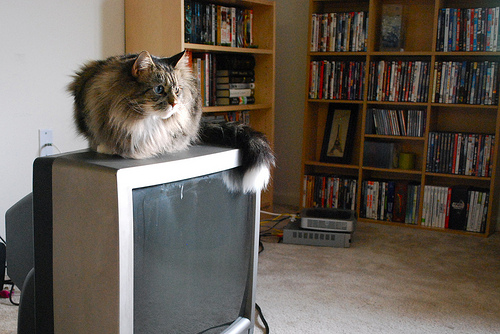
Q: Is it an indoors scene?
A: Yes, it is indoors.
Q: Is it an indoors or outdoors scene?
A: It is indoors.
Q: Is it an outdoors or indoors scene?
A: It is indoors.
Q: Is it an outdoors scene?
A: No, it is indoors.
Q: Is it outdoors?
A: No, it is indoors.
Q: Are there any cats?
A: Yes, there is a cat.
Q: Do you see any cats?
A: Yes, there is a cat.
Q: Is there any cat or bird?
A: Yes, there is a cat.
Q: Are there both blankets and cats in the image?
A: No, there is a cat but no blankets.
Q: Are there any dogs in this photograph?
A: No, there are no dogs.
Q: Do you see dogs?
A: No, there are no dogs.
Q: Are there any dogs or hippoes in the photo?
A: No, there are no dogs or hippoes.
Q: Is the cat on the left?
A: Yes, the cat is on the left of the image.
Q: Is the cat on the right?
A: No, the cat is on the left of the image.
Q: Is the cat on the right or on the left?
A: The cat is on the left of the image.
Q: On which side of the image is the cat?
A: The cat is on the left of the image.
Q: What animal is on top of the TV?
A: The cat is on top of the TV.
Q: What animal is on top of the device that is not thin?
A: The cat is on top of the TV.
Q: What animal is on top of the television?
A: The cat is on top of the TV.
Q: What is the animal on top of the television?
A: The animal is a cat.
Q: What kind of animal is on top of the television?
A: The animal is a cat.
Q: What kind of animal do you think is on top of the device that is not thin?
A: The animal is a cat.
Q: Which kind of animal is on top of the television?
A: The animal is a cat.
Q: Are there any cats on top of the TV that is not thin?
A: Yes, there is a cat on top of the television.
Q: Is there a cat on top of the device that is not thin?
A: Yes, there is a cat on top of the television.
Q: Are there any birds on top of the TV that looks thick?
A: No, there is a cat on top of the TV.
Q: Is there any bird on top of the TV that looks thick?
A: No, there is a cat on top of the TV.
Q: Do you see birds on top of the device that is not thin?
A: No, there is a cat on top of the TV.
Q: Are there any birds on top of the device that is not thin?
A: No, there is a cat on top of the TV.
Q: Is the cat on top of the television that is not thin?
A: Yes, the cat is on top of the TV.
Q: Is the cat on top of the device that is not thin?
A: Yes, the cat is on top of the TV.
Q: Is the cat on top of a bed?
A: No, the cat is on top of the TV.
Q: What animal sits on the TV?
A: The cat sits on the TV.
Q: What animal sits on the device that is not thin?
A: The cat sits on the TV.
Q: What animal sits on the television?
A: The cat sits on the TV.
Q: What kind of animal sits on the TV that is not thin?
A: The animal is a cat.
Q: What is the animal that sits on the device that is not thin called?
A: The animal is a cat.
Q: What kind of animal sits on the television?
A: The animal is a cat.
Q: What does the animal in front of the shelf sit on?
A: The cat sits on the television.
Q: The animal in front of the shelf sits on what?
A: The cat sits on the television.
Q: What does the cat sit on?
A: The cat sits on the television.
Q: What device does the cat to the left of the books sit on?
A: The cat sits on the television.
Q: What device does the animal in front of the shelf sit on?
A: The cat sits on the television.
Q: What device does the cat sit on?
A: The cat sits on the television.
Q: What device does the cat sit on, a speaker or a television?
A: The cat sits on a television.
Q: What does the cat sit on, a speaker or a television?
A: The cat sits on a television.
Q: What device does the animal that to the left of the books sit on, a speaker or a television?
A: The cat sits on a television.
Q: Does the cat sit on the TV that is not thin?
A: Yes, the cat sits on the TV.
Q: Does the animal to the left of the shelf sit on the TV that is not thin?
A: Yes, the cat sits on the TV.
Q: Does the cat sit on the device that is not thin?
A: Yes, the cat sits on the TV.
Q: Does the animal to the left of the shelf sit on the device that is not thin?
A: Yes, the cat sits on the TV.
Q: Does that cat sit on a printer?
A: No, the cat sits on the TV.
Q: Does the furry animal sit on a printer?
A: No, the cat sits on the TV.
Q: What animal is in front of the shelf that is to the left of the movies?
A: The cat is in front of the shelf.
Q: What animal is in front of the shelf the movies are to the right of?
A: The animal is a cat.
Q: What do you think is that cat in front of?
A: The cat is in front of the shelf.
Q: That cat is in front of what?
A: The cat is in front of the shelf.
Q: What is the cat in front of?
A: The cat is in front of the shelf.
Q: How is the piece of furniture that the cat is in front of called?
A: The piece of furniture is a shelf.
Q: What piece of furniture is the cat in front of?
A: The cat is in front of the shelf.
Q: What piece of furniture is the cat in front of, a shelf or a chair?
A: The cat is in front of a shelf.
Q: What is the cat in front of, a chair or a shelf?
A: The cat is in front of a shelf.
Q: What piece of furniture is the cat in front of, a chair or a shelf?
A: The cat is in front of a shelf.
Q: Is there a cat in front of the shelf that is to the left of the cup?
A: Yes, there is a cat in front of the shelf.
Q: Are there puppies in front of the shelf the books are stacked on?
A: No, there is a cat in front of the shelf.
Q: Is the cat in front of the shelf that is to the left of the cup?
A: Yes, the cat is in front of the shelf.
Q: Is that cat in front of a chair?
A: No, the cat is in front of the shelf.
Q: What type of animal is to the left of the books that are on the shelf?
A: The animal is a cat.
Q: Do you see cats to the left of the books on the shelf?
A: Yes, there is a cat to the left of the books.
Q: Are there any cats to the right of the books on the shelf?
A: No, the cat is to the left of the books.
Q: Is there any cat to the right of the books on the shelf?
A: No, the cat is to the left of the books.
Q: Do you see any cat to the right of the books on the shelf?
A: No, the cat is to the left of the books.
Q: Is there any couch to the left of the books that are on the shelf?
A: No, there is a cat to the left of the books.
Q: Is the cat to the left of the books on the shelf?
A: Yes, the cat is to the left of the books.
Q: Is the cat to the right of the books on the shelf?
A: No, the cat is to the left of the books.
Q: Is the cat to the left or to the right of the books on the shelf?
A: The cat is to the left of the books.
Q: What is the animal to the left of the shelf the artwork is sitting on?
A: The animal is a cat.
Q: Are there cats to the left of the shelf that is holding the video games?
A: Yes, there is a cat to the left of the shelf.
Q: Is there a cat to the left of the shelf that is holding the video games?
A: Yes, there is a cat to the left of the shelf.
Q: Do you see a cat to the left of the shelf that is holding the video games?
A: Yes, there is a cat to the left of the shelf.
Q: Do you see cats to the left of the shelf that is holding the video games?
A: Yes, there is a cat to the left of the shelf.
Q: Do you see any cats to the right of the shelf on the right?
A: No, the cat is to the left of the shelf.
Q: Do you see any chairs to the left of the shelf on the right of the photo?
A: No, there is a cat to the left of the shelf.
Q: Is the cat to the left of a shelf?
A: Yes, the cat is to the left of a shelf.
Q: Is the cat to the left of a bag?
A: No, the cat is to the left of a shelf.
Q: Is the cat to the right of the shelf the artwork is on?
A: No, the cat is to the left of the shelf.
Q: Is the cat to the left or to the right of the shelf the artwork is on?
A: The cat is to the left of the shelf.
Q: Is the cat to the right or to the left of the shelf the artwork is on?
A: The cat is to the left of the shelf.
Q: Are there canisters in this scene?
A: No, there are no canisters.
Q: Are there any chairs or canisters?
A: No, there are no canisters or chairs.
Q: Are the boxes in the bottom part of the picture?
A: Yes, the boxes are in the bottom of the image.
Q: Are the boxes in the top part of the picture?
A: No, the boxes are in the bottom of the image.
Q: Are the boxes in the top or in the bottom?
A: The boxes are in the bottom of the image.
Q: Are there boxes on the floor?
A: Yes, there are boxes on the floor.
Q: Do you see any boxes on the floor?
A: Yes, there are boxes on the floor.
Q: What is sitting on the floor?
A: The boxes are sitting on the floor.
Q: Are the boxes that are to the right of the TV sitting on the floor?
A: Yes, the boxes are sitting on the floor.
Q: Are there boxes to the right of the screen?
A: Yes, there are boxes to the right of the screen.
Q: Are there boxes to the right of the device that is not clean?
A: Yes, there are boxes to the right of the screen.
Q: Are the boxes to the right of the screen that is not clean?
A: Yes, the boxes are to the right of the screen.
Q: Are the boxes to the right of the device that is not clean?
A: Yes, the boxes are to the right of the screen.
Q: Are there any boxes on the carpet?
A: Yes, there are boxes on the carpet.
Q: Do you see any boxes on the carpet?
A: Yes, there are boxes on the carpet.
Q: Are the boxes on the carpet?
A: Yes, the boxes are on the carpet.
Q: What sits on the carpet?
A: The boxes sit on the carpet.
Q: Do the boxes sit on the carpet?
A: Yes, the boxes sit on the carpet.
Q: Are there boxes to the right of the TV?
A: Yes, there are boxes to the right of the TV.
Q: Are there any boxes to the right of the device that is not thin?
A: Yes, there are boxes to the right of the TV.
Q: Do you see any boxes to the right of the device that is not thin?
A: Yes, there are boxes to the right of the TV.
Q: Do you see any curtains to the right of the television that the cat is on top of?
A: No, there are boxes to the right of the TV.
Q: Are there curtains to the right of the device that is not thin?
A: No, there are boxes to the right of the TV.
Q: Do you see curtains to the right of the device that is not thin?
A: No, there are boxes to the right of the TV.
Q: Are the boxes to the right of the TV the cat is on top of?
A: Yes, the boxes are to the right of the TV.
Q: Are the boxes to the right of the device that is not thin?
A: Yes, the boxes are to the right of the TV.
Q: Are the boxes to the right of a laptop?
A: No, the boxes are to the right of the TV.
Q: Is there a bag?
A: No, there are no bags.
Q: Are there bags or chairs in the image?
A: No, there are no bags or chairs.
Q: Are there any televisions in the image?
A: Yes, there is a television.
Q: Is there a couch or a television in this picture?
A: Yes, there is a television.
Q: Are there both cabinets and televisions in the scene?
A: No, there is a television but no cabinets.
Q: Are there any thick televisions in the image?
A: Yes, there is a thick television.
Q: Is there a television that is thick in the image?
A: Yes, there is a thick television.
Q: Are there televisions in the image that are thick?
A: Yes, there is a television that is thick.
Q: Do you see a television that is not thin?
A: Yes, there is a thick television.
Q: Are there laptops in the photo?
A: No, there are no laptops.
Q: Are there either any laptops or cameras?
A: No, there are no laptops or cameras.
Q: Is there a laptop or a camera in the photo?
A: No, there are no laptops or cameras.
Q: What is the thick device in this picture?
A: The device is a television.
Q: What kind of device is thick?
A: The device is a television.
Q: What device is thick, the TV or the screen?
A: The TV is thick.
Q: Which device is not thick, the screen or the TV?
A: The screen is not thick.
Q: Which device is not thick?
A: The device is a screen.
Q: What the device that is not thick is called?
A: The device is a screen.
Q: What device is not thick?
A: The device is a screen.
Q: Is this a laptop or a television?
A: This is a television.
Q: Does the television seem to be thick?
A: Yes, the television is thick.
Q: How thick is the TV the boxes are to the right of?
A: The TV is thick.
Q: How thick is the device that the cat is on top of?
A: The TV is thick.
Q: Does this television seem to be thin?
A: No, the television is thick.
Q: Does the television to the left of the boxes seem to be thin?
A: No, the TV is thick.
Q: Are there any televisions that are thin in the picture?
A: No, there is a television but it is thick.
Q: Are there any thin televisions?
A: No, there is a television but it is thick.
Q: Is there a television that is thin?
A: No, there is a television but it is thick.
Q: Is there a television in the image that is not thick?
A: No, there is a television but it is thick.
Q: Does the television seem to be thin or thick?
A: The television is thick.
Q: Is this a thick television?
A: Yes, this is a thick television.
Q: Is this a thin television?
A: No, this is a thick television.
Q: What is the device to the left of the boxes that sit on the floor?
A: The device is a television.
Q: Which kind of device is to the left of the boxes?
A: The device is a television.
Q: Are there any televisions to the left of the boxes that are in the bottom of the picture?
A: Yes, there is a television to the left of the boxes.